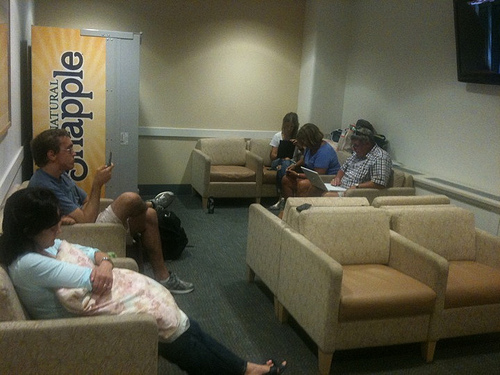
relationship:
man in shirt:
[27, 125, 198, 299] [28, 164, 88, 223]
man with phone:
[27, 125, 198, 299] [106, 151, 118, 171]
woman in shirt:
[2, 185, 291, 374] [6, 236, 106, 322]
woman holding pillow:
[2, 185, 291, 374] [55, 237, 190, 343]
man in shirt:
[315, 124, 394, 205] [338, 142, 395, 200]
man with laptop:
[315, 124, 394, 205] [298, 162, 349, 195]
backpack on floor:
[135, 203, 192, 262] [25, 174, 499, 371]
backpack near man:
[135, 203, 192, 262] [27, 125, 198, 299]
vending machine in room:
[26, 21, 144, 205] [0, 0, 500, 373]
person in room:
[267, 112, 300, 214] [0, 0, 500, 373]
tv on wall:
[452, 1, 500, 89] [341, 5, 499, 206]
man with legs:
[27, 125, 198, 299] [93, 188, 197, 295]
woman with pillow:
[2, 185, 291, 374] [55, 237, 190, 343]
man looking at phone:
[27, 125, 198, 299] [106, 151, 118, 171]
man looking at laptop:
[27, 125, 198, 299] [298, 162, 349, 195]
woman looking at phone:
[281, 119, 341, 214] [284, 162, 299, 183]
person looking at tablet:
[267, 112, 300, 214] [275, 138, 296, 164]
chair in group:
[279, 203, 444, 363] [239, 188, 500, 373]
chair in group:
[384, 202, 499, 363] [239, 188, 500, 373]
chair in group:
[373, 195, 453, 207] [239, 188, 500, 373]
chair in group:
[241, 194, 373, 315] [239, 188, 500, 373]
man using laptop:
[315, 124, 394, 205] [298, 162, 349, 195]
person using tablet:
[267, 112, 300, 214] [275, 138, 296, 164]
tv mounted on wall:
[452, 1, 500, 89] [341, 5, 499, 206]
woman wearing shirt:
[2, 185, 291, 374] [6, 236, 106, 322]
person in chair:
[267, 112, 300, 214] [247, 133, 293, 206]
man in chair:
[27, 125, 198, 299] [7, 180, 137, 260]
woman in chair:
[2, 185, 291, 374] [1, 250, 167, 374]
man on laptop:
[27, 125, 198, 299] [298, 162, 349, 195]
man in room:
[27, 125, 198, 299] [0, 0, 500, 373]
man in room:
[315, 124, 394, 205] [0, 0, 500, 373]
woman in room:
[2, 185, 291, 374] [0, 0, 500, 373]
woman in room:
[281, 119, 341, 214] [0, 0, 500, 373]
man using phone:
[27, 125, 198, 299] [106, 151, 118, 171]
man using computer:
[315, 124, 394, 205] [298, 162, 349, 195]